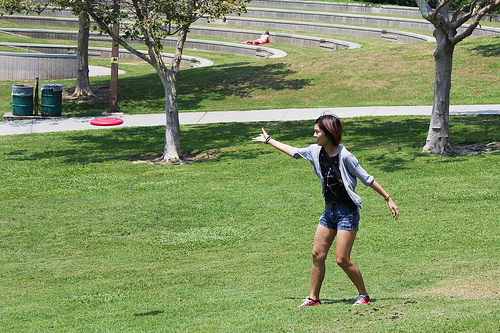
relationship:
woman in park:
[253, 115, 401, 307] [0, 1, 497, 332]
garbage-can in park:
[11, 85, 35, 118] [0, 1, 497, 332]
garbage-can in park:
[42, 83, 63, 118] [0, 1, 497, 332]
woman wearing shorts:
[253, 115, 401, 307] [319, 199, 359, 231]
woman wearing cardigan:
[253, 115, 401, 307] [292, 144, 374, 208]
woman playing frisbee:
[253, 115, 401, 307] [90, 117, 123, 125]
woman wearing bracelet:
[253, 115, 401, 307] [265, 135, 273, 144]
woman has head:
[253, 115, 401, 307] [313, 115, 343, 148]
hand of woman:
[252, 128, 269, 142] [253, 115, 401, 307]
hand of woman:
[387, 199, 399, 220] [253, 115, 401, 307]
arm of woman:
[350, 156, 390, 200] [253, 115, 401, 307]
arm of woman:
[270, 139, 314, 159] [253, 115, 401, 307]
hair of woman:
[318, 115, 343, 145] [253, 115, 401, 307]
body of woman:
[304, 144, 365, 298] [253, 115, 401, 307]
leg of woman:
[337, 224, 365, 295] [253, 115, 401, 307]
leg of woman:
[310, 223, 336, 299] [253, 115, 401, 307]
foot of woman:
[299, 297, 322, 307] [253, 115, 401, 307]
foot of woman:
[353, 295, 369, 306] [253, 115, 401, 307]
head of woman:
[313, 115, 343, 148] [253, 115, 401, 307]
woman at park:
[253, 115, 401, 307] [0, 1, 497, 332]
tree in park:
[67, 1, 249, 163] [0, 1, 497, 332]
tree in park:
[415, 1, 498, 154] [0, 1, 497, 332]